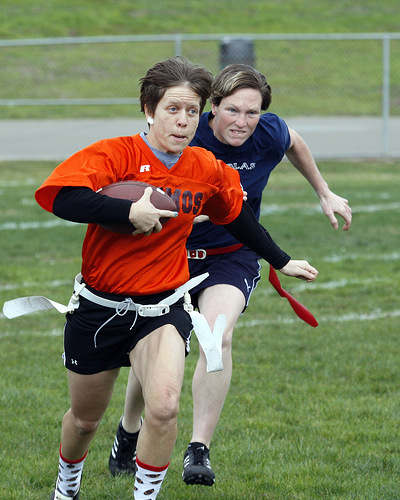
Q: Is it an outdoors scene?
A: Yes, it is outdoors.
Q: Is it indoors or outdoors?
A: It is outdoors.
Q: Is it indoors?
A: No, it is outdoors.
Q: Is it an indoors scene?
A: No, it is outdoors.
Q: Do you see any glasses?
A: No, there are no glasses.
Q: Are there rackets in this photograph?
A: No, there are no rackets.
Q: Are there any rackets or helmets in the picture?
A: No, there are no rackets or helmets.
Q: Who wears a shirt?
A: The player wears a shirt.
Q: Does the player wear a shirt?
A: Yes, the player wears a shirt.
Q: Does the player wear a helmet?
A: No, the player wears a shirt.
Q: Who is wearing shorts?
A: The player is wearing shorts.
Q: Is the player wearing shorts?
A: Yes, the player is wearing shorts.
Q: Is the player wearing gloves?
A: No, the player is wearing shorts.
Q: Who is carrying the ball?
A: The player is carrying the ball.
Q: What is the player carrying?
A: The player is carrying a ball.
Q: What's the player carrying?
A: The player is carrying a ball.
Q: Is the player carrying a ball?
A: Yes, the player is carrying a ball.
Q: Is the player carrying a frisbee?
A: No, the player is carrying a ball.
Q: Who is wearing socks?
A: The player is wearing socks.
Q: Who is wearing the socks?
A: The player is wearing socks.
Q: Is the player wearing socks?
A: Yes, the player is wearing socks.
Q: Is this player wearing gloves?
A: No, the player is wearing socks.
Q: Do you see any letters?
A: Yes, there are letters.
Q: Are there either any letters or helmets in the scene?
A: Yes, there are letters.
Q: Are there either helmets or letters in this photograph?
A: Yes, there are letters.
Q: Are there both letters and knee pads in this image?
A: No, there are letters but no knee pads.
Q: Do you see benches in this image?
A: No, there are no benches.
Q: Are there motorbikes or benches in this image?
A: No, there are no benches or motorbikes.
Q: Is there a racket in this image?
A: No, there are no rackets.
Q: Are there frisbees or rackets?
A: No, there are no rackets or frisbees.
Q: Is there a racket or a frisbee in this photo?
A: No, there are no rackets or frisbees.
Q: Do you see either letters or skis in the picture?
A: Yes, there are letters.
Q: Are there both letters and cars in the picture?
A: No, there are letters but no cars.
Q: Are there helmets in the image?
A: No, there are no helmets.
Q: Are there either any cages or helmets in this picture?
A: No, there are no helmets or cages.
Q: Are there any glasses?
A: No, there are no glasses.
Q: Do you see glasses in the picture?
A: No, there are no glasses.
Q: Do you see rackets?
A: No, there are no rackets.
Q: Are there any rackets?
A: No, there are no rackets.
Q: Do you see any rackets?
A: No, there are no rackets.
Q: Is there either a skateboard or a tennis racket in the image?
A: No, there are no rackets or skateboards.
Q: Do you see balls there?
A: Yes, there is a ball.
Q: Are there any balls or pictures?
A: Yes, there is a ball.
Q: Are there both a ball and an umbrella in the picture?
A: No, there is a ball but no umbrellas.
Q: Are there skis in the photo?
A: No, there are no skis.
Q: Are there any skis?
A: No, there are no skis.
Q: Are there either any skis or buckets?
A: No, there are no skis or buckets.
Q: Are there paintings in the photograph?
A: No, there are no paintings.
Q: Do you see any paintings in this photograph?
A: No, there are no paintings.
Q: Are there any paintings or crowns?
A: No, there are no paintings or crowns.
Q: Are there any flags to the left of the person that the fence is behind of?
A: Yes, there are flags to the left of the person.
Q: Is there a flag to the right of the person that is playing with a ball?
A: No, the flags are to the left of the person.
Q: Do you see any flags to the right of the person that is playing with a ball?
A: No, the flags are to the left of the person.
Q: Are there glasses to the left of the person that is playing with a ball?
A: No, there are flags to the left of the person.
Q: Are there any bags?
A: No, there are no bags.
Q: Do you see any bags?
A: No, there are no bags.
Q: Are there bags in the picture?
A: No, there are no bags.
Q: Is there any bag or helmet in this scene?
A: No, there are no bags or helmets.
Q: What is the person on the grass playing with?
A: The person is playing with a ball.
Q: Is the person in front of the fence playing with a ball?
A: Yes, the person is playing with a ball.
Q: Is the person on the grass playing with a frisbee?
A: No, the person is playing with a ball.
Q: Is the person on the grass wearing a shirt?
A: Yes, the person is wearing a shirt.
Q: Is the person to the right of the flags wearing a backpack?
A: No, the person is wearing a shirt.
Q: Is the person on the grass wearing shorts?
A: Yes, the person is wearing shorts.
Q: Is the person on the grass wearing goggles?
A: No, the person is wearing shorts.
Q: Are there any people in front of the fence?
A: Yes, there is a person in front of the fence.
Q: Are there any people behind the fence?
A: No, the person is in front of the fence.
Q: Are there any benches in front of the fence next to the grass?
A: No, there is a person in front of the fence.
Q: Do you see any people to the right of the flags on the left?
A: Yes, there is a person to the right of the flags.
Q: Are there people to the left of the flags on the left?
A: No, the person is to the right of the flags.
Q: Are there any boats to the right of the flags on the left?
A: No, there is a person to the right of the flags.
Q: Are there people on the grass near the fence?
A: Yes, there is a person on the grass.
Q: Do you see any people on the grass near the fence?
A: Yes, there is a person on the grass.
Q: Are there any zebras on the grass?
A: No, there is a person on the grass.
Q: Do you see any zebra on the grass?
A: No, there is a person on the grass.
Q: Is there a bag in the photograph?
A: No, there are no bags.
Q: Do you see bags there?
A: No, there are no bags.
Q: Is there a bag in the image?
A: No, there are no bags.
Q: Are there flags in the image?
A: Yes, there is a flag.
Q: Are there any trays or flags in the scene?
A: Yes, there is a flag.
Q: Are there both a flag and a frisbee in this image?
A: No, there is a flag but no frisbees.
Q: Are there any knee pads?
A: No, there are no knee pads.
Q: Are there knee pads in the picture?
A: No, there are no knee pads.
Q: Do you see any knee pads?
A: No, there are no knee pads.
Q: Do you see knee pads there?
A: No, there are no knee pads.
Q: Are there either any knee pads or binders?
A: No, there are no knee pads or binders.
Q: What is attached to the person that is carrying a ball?
A: The flag is attached to the player.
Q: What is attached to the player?
A: The flag is attached to the player.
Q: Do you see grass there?
A: Yes, there is grass.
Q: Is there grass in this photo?
A: Yes, there is grass.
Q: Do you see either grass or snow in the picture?
A: Yes, there is grass.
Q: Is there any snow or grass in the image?
A: Yes, there is grass.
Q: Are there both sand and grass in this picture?
A: No, there is grass but no sand.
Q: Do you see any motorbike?
A: No, there are no motorcycles.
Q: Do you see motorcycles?
A: No, there are no motorcycles.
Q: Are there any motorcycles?
A: No, there are no motorcycles.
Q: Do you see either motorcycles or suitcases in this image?
A: No, there are no motorcycles or suitcases.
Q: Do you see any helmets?
A: No, there are no helmets.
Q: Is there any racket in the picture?
A: No, there are no rackets.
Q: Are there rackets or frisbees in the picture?
A: No, there are no rackets or frisbees.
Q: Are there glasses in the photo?
A: No, there are no glasses.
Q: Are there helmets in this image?
A: No, there are no helmets.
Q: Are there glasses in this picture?
A: No, there are no glasses.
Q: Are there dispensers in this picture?
A: No, there are no dispensers.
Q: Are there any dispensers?
A: No, there are no dispensers.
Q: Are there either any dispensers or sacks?
A: No, there are no dispensers or sacks.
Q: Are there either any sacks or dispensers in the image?
A: No, there are no dispensers or sacks.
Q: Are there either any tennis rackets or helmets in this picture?
A: No, there are no tennis rackets or helmets.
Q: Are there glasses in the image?
A: No, there are no glasses.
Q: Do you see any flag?
A: Yes, there is a flag.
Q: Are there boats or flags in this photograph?
A: Yes, there is a flag.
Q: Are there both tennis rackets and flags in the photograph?
A: No, there is a flag but no rackets.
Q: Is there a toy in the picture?
A: No, there are no toys.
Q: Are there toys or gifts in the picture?
A: No, there are no toys or gifts.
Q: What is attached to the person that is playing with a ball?
A: The flag is attached to the person.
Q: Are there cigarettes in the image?
A: No, there are no cigarettes.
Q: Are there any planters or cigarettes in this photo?
A: No, there are no cigarettes or planters.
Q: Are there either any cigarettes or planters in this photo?
A: No, there are no cigarettes or planters.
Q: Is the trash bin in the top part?
A: Yes, the trash bin is in the top of the image.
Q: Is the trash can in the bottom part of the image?
A: No, the trash can is in the top of the image.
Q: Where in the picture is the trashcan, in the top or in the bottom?
A: The trashcan is in the top of the image.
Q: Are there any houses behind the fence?
A: No, there is a trash can behind the fence.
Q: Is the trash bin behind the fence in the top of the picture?
A: Yes, the trash bin is behind the fence.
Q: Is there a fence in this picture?
A: Yes, there is a fence.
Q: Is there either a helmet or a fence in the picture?
A: Yes, there is a fence.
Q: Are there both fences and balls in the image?
A: Yes, there are both a fence and a ball.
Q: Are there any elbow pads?
A: No, there are no elbow pads.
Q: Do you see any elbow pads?
A: No, there are no elbow pads.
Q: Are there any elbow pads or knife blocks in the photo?
A: No, there are no elbow pads or knife blocks.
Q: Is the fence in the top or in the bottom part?
A: The fence is in the top of the image.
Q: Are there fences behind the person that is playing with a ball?
A: Yes, there is a fence behind the person.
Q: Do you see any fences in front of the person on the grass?
A: No, the fence is behind the person.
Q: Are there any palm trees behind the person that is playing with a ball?
A: No, there is a fence behind the person.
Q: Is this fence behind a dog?
A: No, the fence is behind the person.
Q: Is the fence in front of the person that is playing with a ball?
A: No, the fence is behind the person.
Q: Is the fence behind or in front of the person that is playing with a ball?
A: The fence is behind the person.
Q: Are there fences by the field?
A: Yes, there is a fence by the field.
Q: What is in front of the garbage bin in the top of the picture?
A: The fence is in front of the garbage can.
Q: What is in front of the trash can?
A: The fence is in front of the garbage can.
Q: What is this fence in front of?
A: The fence is in front of the garbage bin.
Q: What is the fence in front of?
A: The fence is in front of the garbage bin.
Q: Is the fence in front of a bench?
A: No, the fence is in front of a trash can.